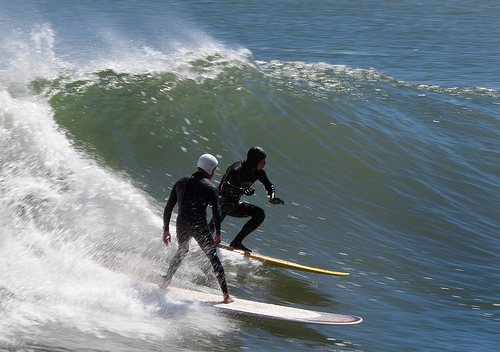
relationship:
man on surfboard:
[151, 151, 234, 306] [147, 284, 361, 332]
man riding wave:
[151, 151, 234, 306] [36, 153, 113, 349]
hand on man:
[258, 188, 292, 214] [218, 143, 284, 253]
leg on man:
[198, 243, 246, 304] [151, 151, 234, 306]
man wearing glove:
[218, 143, 284, 253] [263, 186, 286, 208]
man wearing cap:
[151, 151, 234, 306] [195, 149, 219, 176]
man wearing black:
[151, 151, 234, 306] [165, 176, 228, 300]